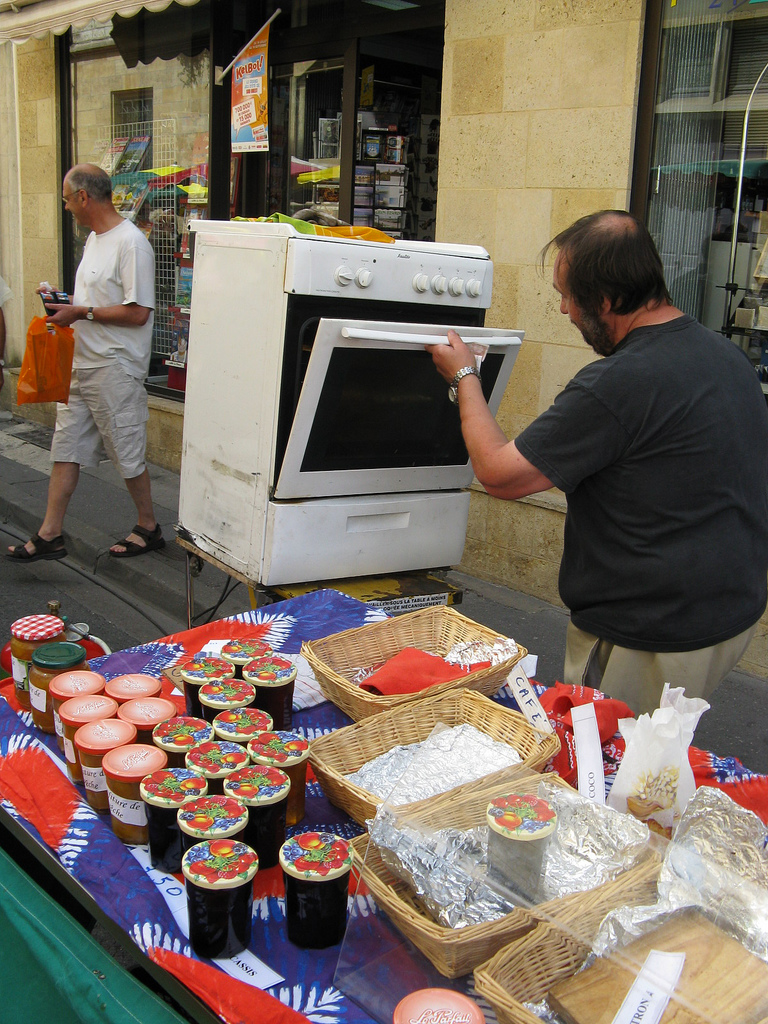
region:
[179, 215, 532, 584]
A white stove on a cart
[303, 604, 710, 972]
Wicker baskets on a table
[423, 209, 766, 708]
A man opening an oven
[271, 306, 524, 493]
A door on an oven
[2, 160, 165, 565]
A man walking on the sidewalk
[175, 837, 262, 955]
A jar on a table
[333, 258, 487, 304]
Knobs on a stove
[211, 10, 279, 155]
A flag on a building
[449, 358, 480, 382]
A watch on a man's wrist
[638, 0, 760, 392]
A window on a building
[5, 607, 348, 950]
the jars on the table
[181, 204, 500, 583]
the oven is white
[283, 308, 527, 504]
the door of the oven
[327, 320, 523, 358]
the handle on the door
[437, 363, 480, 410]
the watch on the wrist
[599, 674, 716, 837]
the bag on the table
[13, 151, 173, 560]
the man holding the bag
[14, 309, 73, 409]
the bag is orange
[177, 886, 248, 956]
jar on the table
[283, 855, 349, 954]
jar on the table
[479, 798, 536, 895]
jar on the table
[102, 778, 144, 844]
jar on the table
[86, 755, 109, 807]
jar on the table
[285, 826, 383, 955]
a jar on the table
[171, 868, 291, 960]
a jar on the table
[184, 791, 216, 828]
a jar on the table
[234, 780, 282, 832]
a jar on the table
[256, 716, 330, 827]
va jar on the table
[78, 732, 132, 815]
a jar on the table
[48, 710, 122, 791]
a jar on the table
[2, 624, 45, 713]
a jar on the table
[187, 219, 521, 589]
a white stove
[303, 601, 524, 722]
a brown wicker basket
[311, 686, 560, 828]
a brown wicker basket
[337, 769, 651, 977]
a brown wicker basket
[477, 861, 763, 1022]
a brown wicker basket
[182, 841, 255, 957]
a glass jar of jelly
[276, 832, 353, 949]
a glass jar of jelly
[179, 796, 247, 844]
a glass jar of jelly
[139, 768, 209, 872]
a glass jar of jelly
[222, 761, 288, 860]
a glass jar of jelly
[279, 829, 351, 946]
A vessel made for storing jam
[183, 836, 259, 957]
A vessel made for storing food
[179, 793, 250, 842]
A vessel made for storing food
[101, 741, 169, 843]
A vessel made for storing food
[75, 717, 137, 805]
A vessel made for storing food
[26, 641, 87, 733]
A vessel made for storing food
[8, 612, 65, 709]
A vessel made for storing food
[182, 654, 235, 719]
A vessel made for storing food